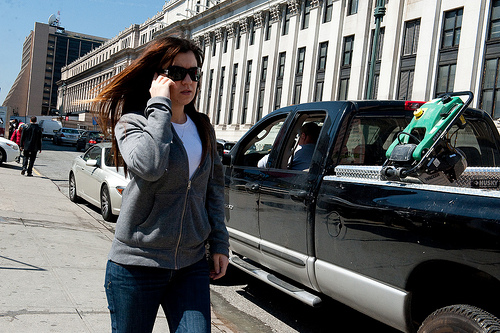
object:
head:
[148, 36, 204, 112]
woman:
[104, 35, 230, 333]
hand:
[207, 251, 229, 282]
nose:
[180, 73, 194, 87]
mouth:
[178, 87, 194, 97]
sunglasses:
[158, 63, 203, 83]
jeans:
[104, 258, 210, 332]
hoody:
[107, 96, 230, 268]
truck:
[222, 99, 499, 331]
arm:
[114, 97, 171, 182]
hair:
[92, 36, 213, 171]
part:
[110, 292, 138, 307]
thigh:
[104, 281, 161, 333]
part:
[1, 220, 33, 270]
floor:
[0, 160, 228, 332]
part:
[161, 90, 169, 96]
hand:
[147, 73, 175, 99]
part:
[19, 222, 39, 239]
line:
[1, 184, 98, 333]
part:
[161, 228, 175, 244]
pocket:
[184, 192, 211, 248]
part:
[67, 134, 74, 139]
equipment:
[382, 91, 471, 185]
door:
[298, 186, 410, 316]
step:
[230, 252, 323, 308]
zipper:
[172, 176, 195, 271]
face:
[169, 51, 202, 103]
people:
[8, 115, 43, 177]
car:
[67, 141, 135, 220]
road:
[15, 139, 399, 332]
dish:
[46, 10, 63, 28]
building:
[0, 21, 112, 115]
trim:
[225, 225, 407, 333]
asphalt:
[23, 138, 88, 191]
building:
[54, 0, 500, 142]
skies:
[0, 1, 172, 105]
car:
[51, 126, 84, 146]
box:
[333, 166, 499, 195]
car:
[0, 136, 21, 167]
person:
[275, 122, 318, 170]